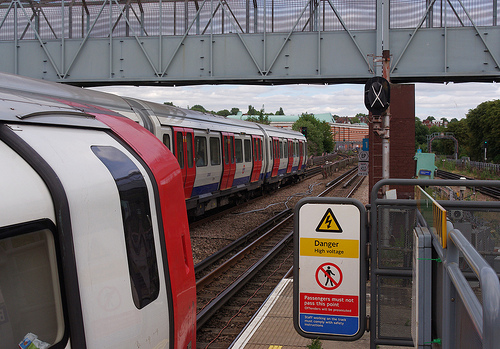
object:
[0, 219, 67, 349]
window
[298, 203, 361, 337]
signage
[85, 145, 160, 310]
window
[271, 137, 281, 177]
door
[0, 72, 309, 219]
train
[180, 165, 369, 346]
track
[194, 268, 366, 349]
ground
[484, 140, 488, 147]
light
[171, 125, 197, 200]
door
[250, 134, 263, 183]
door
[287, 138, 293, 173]
door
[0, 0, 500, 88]
bridge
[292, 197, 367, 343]
emblem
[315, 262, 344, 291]
cirlce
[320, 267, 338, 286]
line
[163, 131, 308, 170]
window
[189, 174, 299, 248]
wheels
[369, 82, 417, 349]
pole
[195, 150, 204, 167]
person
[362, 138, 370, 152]
sign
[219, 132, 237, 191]
door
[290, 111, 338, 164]
tree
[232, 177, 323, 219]
cords